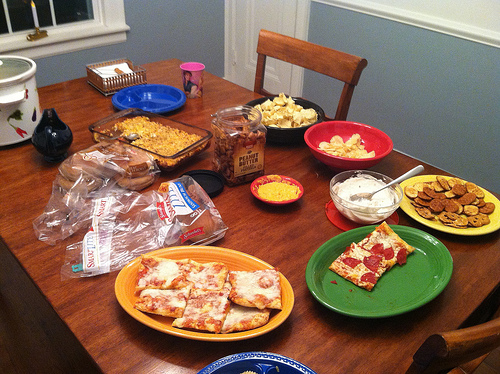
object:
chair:
[248, 26, 369, 123]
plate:
[303, 222, 455, 319]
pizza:
[327, 240, 392, 295]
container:
[210, 103, 269, 185]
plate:
[395, 170, 500, 237]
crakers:
[460, 198, 483, 220]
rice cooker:
[0, 55, 42, 147]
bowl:
[247, 171, 304, 205]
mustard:
[259, 177, 297, 202]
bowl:
[302, 116, 394, 173]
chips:
[324, 134, 350, 146]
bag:
[56, 175, 231, 285]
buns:
[161, 176, 221, 242]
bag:
[32, 143, 161, 242]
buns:
[59, 147, 106, 182]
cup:
[179, 62, 209, 101]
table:
[1, 54, 500, 373]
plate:
[114, 82, 184, 113]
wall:
[302, 0, 500, 195]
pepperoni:
[342, 257, 362, 271]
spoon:
[351, 163, 425, 201]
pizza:
[225, 268, 281, 310]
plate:
[112, 245, 295, 342]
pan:
[86, 109, 213, 168]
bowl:
[245, 93, 325, 136]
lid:
[179, 169, 229, 200]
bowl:
[327, 169, 405, 221]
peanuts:
[210, 112, 266, 187]